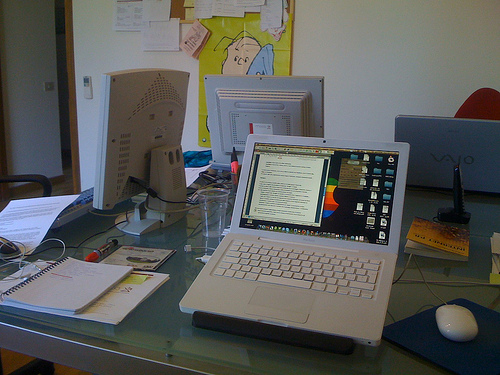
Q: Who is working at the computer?
A: No one.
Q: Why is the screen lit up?
A: The computer is on.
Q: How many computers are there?
A: Four.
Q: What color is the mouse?
A: White.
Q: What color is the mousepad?
A: Blue.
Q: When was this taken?
A: Daytime.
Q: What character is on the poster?
A: Linus.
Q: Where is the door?
A: In the corner.